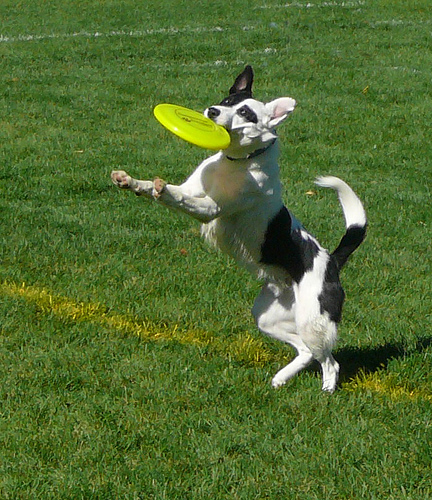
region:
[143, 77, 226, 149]
yellow Frisbee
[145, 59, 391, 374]
black and white dog catching Frisbee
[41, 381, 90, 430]
short green and yellow grass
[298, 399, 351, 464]
short green and yellow grass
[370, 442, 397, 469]
short green and yellow grass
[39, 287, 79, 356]
short green and yellow grass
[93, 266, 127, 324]
short green and yellow grass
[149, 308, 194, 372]
short green and yellow grass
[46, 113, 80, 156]
short green and yellow grass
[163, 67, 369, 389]
Dog with frisbee in the mouth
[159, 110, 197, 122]
A frisbee in the mouth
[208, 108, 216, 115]
The nose of a dog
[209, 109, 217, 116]
Black nose of a dog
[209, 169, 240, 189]
Shadow of frisbee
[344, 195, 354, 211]
The dog's white tail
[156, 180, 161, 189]
The pad on the paw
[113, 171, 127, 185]
The paw of the dog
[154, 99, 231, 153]
yellow frisbee in the dog's mouth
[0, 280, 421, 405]
yellow line spray painted in the grass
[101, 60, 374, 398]
black and white dog catching a frisbee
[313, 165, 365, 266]
the dog has a black and white tail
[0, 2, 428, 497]
bright green grass on the ground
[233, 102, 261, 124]
the dog has a black spot on its eye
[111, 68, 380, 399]
the dog is standing on its hind legs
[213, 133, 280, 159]
black collar around the dog's neck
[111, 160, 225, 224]
the dog's front legs are outward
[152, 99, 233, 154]
yellow frisbee with brown writing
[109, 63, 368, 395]
a black and white dog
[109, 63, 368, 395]
dog is catching a frisbee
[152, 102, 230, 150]
round yellow frisbee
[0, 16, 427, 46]
white stripe painted on grass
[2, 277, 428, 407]
yellow stripe painted on grass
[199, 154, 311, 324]
shadow on the body of the dog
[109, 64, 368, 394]
yellow frisbee in dog's mouth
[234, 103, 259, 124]
black patch around dog's eye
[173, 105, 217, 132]
logo on top of a frisbee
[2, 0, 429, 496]
green grassy covered field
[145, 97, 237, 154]
chartreuse frisbee lightly caught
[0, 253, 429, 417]
a yellow line in the grass, not inadvertently created by dog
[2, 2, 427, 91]
several broken white chalk lines, also on grass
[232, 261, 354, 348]
two cow colour hind haunches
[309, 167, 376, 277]
a tail almost perfectly split black from white, down by halves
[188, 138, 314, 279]
an elongated frisbee shadow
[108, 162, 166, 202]
two pink paw pad bottoms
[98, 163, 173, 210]
two paws with pink paw pads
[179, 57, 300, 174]
head split in monochrome almost as evenly as tail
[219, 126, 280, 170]
and a black collar with light colour details completes the ensemble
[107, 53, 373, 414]
dog with Frisbee in mouthdog with Frisbee in mouth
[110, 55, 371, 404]
dog with Frisbee in mouth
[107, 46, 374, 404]
dog with Frisbee in mouth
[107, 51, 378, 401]
dog with Frisbee in mouth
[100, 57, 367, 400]
dog with Frisbee in mouth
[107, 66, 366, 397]
dog with Frisbee in mouth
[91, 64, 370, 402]
dog with Frisbee in mouth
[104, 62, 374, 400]
dog with Frisbee in mouth